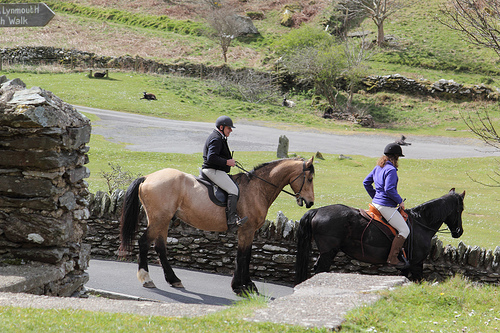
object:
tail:
[114, 168, 149, 264]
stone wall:
[0, 73, 120, 305]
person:
[361, 135, 412, 270]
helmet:
[214, 114, 237, 136]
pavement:
[81, 249, 296, 307]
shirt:
[361, 159, 406, 210]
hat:
[379, 142, 409, 159]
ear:
[303, 152, 315, 167]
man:
[195, 104, 250, 234]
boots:
[186, 175, 258, 235]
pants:
[371, 197, 410, 239]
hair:
[376, 153, 401, 168]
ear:
[447, 185, 458, 195]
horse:
[289, 182, 474, 287]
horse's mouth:
[296, 197, 310, 209]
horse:
[117, 149, 316, 298]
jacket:
[201, 129, 235, 173]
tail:
[289, 203, 320, 288]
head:
[290, 155, 316, 210]